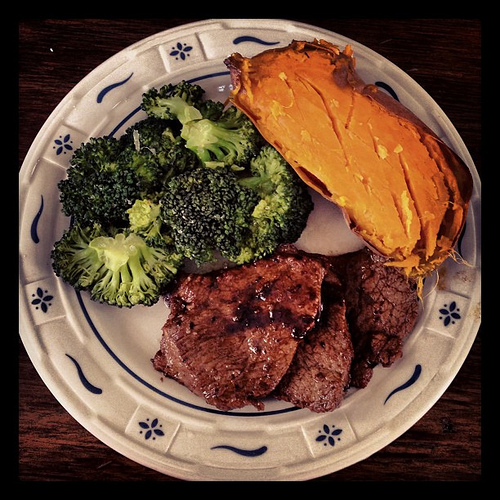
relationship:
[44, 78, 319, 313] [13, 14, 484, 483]
broccoli on plate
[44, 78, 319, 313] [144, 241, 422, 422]
broccoli next to meat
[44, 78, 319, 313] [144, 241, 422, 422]
broccoli next to red meat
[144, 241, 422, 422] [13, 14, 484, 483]
steak on a plate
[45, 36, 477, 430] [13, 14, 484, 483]
food on a plate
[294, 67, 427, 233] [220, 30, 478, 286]
marks are on potato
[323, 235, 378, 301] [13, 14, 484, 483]
sauce on side plate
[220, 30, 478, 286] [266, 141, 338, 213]
sweet potato has skin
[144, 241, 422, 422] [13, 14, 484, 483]
meat sitting on plate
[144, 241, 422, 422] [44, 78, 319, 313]
meat with broccoli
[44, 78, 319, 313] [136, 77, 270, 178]
broccoli in spears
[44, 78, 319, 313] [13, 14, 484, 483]
broccoli are on top a plate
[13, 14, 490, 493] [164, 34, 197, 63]
plate with flower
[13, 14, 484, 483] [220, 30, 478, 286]
plate holding sweet potato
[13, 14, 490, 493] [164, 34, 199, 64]
plate has flower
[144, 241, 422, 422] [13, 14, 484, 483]
meat on a plate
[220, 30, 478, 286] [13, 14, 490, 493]
sweet potato on side of plate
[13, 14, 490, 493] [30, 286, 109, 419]
plate has blue pattern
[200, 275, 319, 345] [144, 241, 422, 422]
gravy on top meat